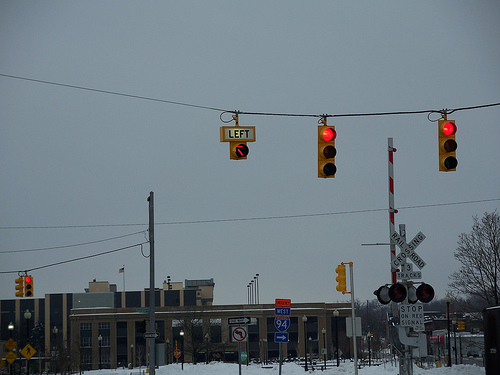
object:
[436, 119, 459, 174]
traffic light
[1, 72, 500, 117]
wire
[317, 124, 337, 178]
traffic light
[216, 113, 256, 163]
traffic light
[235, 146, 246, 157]
arrow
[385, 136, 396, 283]
pole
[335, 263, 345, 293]
traffic light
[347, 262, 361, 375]
pole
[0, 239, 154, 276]
wire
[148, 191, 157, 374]
pole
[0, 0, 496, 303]
sky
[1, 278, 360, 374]
building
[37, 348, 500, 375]
ground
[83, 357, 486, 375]
snow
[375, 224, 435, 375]
railroad crossing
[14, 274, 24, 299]
traffic light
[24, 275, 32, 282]
stoplight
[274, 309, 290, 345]
sign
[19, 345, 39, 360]
sign